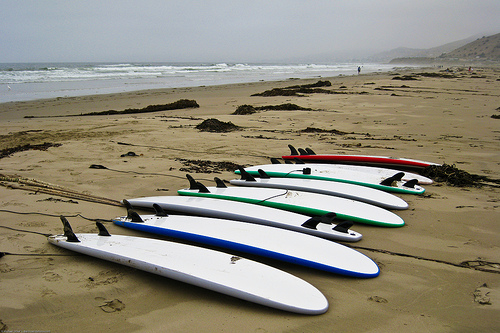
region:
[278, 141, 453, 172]
red and white surfboard laying on beach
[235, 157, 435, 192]
green and white surfboard on sand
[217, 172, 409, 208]
gray and white surfboard next to surfboard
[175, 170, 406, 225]
green and white surfboard on beach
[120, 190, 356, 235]
gray and white surfboard laying down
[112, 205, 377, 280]
dark blue and white surfboard on sand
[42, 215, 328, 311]
gray and white surfboard at the end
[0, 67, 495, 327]
light brown colored sandy beach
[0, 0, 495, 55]
dark hazy sky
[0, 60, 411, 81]
calm ocean wave near shore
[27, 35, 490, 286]
Picture is taken in the beach.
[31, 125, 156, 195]
Sand is brown color.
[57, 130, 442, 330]
7 surfing-boards are seen.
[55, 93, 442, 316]
Surfing board is kept inverted.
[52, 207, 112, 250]
black three knobs at the back of surfing board.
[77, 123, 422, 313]
Surfing board are mainly white.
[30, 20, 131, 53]
Sky is grey color.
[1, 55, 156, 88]
Water is blue color.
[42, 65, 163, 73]
Waves are white color.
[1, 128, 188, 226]
Marking is seen in sand.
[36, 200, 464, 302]
surfboards on the beach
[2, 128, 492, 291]
8 surfboards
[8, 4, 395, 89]
sky is grayish blue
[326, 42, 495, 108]
2 people in the distance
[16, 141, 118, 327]
footprints on the beach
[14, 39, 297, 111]
white caps on the waves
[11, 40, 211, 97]
water is blue with white caps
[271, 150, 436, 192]
red surfboard on the end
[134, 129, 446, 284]
2 green surfboards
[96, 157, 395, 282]
1 blue surfboard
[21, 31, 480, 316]
Picture of surfboards on beach.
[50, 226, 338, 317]
The first surfboard is white.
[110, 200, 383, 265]
Second surfboard blue and white.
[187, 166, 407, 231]
Fourth surfboard green and white.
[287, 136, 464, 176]
Last surfboard red and white.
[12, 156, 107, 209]
Tracks on the beach.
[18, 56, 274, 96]
Choppy waves on ocean.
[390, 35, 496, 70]
Hills on right in the background.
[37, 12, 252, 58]
The sky is overcast.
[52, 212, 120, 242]
Fins on back of first surfboard.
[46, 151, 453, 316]
Eight surf boards on a beach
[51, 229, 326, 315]
A gray surf board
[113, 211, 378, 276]
A blue surf board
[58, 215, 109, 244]
Three surf board fins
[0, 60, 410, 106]
Waves in the ocean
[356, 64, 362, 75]
A person in the distance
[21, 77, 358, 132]
Piles of seaweed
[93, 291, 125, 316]
A footprint in the sand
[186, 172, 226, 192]
Three surf board fins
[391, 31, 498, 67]
A distant hill